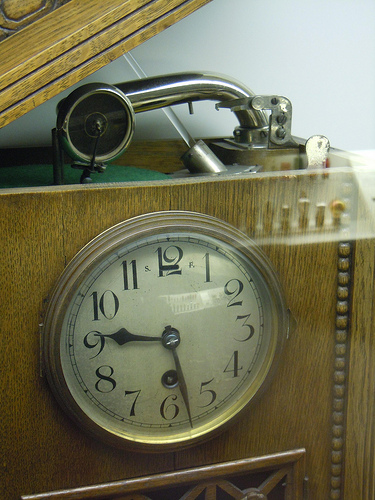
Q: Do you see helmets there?
A: No, there are no helmets.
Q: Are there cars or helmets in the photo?
A: No, there are no helmets or cars.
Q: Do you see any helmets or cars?
A: No, there are no helmets or cars.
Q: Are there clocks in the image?
A: Yes, there is a clock.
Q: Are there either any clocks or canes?
A: Yes, there is a clock.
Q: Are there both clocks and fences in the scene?
A: No, there is a clock but no fences.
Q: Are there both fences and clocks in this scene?
A: No, there is a clock but no fences.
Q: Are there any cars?
A: No, there are no cars.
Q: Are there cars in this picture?
A: No, there are no cars.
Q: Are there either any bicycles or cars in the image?
A: No, there are no cars or bicycles.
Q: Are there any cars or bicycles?
A: No, there are no cars or bicycles.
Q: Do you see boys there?
A: No, there are no boys.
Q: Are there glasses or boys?
A: No, there are no boys or glasses.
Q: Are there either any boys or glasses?
A: No, there are no boys or glasses.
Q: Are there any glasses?
A: No, there are no glasses.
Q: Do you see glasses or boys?
A: No, there are no glasses or boys.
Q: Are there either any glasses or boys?
A: No, there are no glasses or boys.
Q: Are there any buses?
A: No, there are no buses.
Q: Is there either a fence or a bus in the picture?
A: No, there are no buses or fences.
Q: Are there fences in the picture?
A: No, there are no fences.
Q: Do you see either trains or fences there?
A: No, there are no fences or trains.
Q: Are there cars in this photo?
A: No, there are no cars.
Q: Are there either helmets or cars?
A: No, there are no cars or helmets.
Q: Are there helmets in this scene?
A: No, there are no helmets.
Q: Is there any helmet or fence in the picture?
A: No, there are no helmets or fences.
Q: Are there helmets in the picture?
A: No, there are no helmets.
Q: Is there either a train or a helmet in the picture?
A: No, there are no helmets or trains.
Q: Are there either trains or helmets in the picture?
A: No, there are no helmets or trains.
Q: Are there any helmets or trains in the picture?
A: No, there are no helmets or trains.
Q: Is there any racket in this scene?
A: No, there are no rackets.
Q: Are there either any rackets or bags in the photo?
A: No, there are no rackets or bags.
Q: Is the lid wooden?
A: Yes, the lid is wooden.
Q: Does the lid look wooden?
A: Yes, the lid is wooden.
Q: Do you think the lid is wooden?
A: Yes, the lid is wooden.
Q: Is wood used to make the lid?
A: Yes, the lid is made of wood.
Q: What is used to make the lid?
A: The lid is made of wood.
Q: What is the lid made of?
A: The lid is made of wood.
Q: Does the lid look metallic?
A: No, the lid is wooden.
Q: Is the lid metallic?
A: No, the lid is wooden.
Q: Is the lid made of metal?
A: No, the lid is made of wood.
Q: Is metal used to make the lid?
A: No, the lid is made of wood.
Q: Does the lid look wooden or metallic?
A: The lid is wooden.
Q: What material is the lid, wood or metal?
A: The lid is made of wood.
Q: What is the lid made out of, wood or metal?
A: The lid is made of wood.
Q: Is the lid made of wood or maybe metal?
A: The lid is made of wood.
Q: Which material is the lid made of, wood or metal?
A: The lid is made of wood.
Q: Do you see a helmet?
A: No, there are no helmets.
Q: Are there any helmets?
A: No, there are no helmets.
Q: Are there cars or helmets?
A: No, there are no helmets or cars.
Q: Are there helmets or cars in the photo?
A: No, there are no helmets or cars.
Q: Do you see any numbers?
A: Yes, there are numbers.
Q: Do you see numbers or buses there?
A: Yes, there are numbers.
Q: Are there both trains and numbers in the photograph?
A: No, there are numbers but no trains.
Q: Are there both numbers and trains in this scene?
A: No, there are numbers but no trains.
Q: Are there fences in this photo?
A: No, there are no fences.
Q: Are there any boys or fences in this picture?
A: No, there are no fences or boys.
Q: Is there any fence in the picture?
A: No, there are no fences.